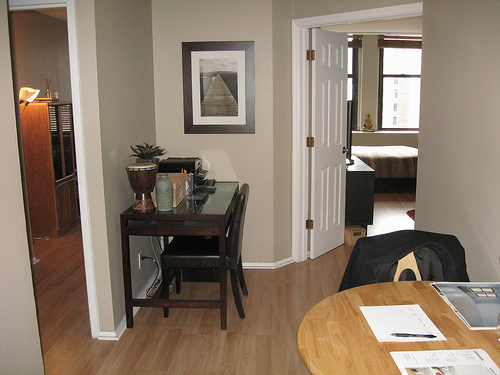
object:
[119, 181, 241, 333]
desk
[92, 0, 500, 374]
room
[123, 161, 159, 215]
bongo drum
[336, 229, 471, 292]
jacket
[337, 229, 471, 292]
chair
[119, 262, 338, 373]
floor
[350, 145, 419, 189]
bed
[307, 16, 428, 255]
bedroom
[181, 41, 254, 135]
picture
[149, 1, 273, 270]
wall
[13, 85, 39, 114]
lamp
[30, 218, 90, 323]
floor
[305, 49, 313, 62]
hinges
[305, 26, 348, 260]
door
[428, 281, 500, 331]
papers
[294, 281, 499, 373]
table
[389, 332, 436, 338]
pen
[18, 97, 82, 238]
cabinet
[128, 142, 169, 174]
plant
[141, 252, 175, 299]
cord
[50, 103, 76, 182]
reflection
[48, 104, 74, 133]
window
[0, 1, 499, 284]
walls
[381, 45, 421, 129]
sunlight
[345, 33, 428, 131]
window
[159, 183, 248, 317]
chair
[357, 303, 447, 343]
paper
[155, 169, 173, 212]
vase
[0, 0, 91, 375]
hallway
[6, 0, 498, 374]
rooms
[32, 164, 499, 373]
floors